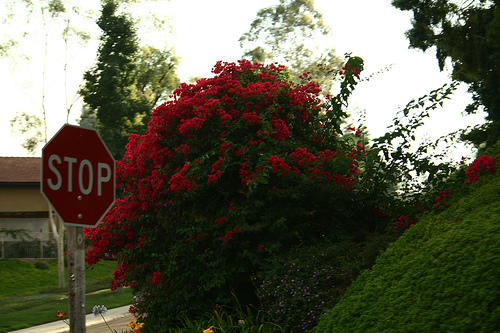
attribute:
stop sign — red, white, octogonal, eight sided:
[41, 124, 117, 227]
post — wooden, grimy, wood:
[64, 221, 87, 332]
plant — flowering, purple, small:
[83, 57, 363, 314]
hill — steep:
[312, 183, 499, 333]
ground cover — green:
[317, 181, 499, 331]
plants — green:
[83, 0, 499, 333]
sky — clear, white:
[1, 0, 493, 199]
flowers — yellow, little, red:
[127, 319, 219, 332]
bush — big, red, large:
[83, 54, 365, 333]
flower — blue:
[91, 305, 107, 316]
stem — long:
[102, 315, 113, 332]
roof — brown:
[1, 158, 61, 213]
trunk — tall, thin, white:
[46, 202, 67, 286]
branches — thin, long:
[1, 4, 94, 155]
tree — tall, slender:
[1, 0, 98, 156]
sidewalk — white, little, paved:
[2, 301, 141, 332]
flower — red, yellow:
[57, 310, 66, 320]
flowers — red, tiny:
[84, 58, 365, 315]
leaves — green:
[132, 112, 382, 308]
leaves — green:
[392, 0, 499, 149]